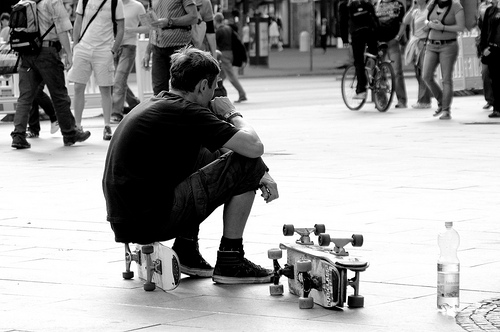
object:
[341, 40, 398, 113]
bike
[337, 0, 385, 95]
person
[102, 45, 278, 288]
man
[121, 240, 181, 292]
skateboard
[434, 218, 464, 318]
bottle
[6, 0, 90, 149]
person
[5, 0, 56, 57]
backpack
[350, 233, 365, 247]
wheels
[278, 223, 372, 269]
skateboard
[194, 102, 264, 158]
arm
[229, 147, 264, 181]
knee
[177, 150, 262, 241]
leg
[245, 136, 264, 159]
elbow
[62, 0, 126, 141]
person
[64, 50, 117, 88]
shorts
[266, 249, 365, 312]
skateboards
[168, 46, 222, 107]
face